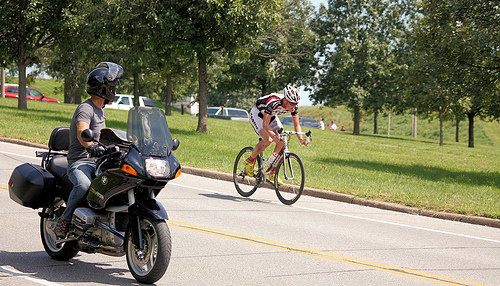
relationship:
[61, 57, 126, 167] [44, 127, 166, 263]
man on motorcycle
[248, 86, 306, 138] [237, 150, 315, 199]
person on bike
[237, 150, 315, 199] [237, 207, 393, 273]
bike on road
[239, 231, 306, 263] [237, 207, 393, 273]
line on road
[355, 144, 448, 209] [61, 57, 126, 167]
grass near man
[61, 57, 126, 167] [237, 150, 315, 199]
man on bike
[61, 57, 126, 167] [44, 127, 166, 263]
man riding motorcycle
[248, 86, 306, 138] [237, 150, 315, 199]
person riding bike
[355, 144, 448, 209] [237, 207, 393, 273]
grass near road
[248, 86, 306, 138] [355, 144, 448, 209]
person near grass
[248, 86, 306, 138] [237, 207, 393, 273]
person on road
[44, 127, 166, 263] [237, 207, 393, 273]
motorcycle in road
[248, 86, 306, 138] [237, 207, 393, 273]
person in road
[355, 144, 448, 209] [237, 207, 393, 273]
grass by road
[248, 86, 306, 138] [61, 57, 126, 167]
person near man